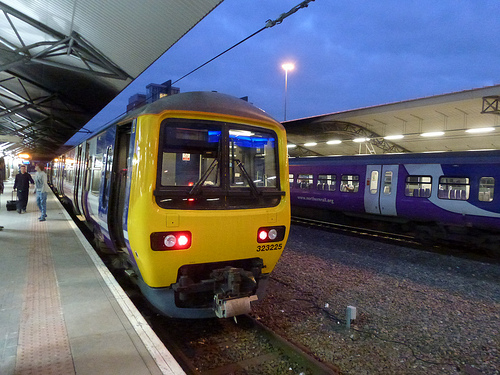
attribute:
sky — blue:
[61, 2, 498, 157]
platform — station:
[2, 180, 165, 373]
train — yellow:
[83, 100, 310, 319]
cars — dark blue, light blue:
[291, 117, 497, 264]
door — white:
[360, 162, 404, 217]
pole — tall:
[281, 74, 288, 124]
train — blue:
[282, 133, 497, 240]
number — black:
[254, 238, 286, 256]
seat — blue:
[405, 186, 436, 201]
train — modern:
[5, 74, 326, 337]